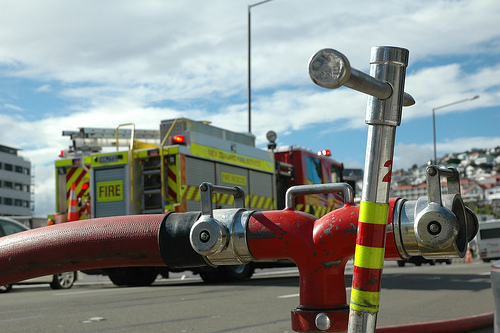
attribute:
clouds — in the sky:
[22, 14, 474, 155]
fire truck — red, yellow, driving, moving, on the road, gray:
[54, 117, 355, 295]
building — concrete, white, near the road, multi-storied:
[0, 145, 39, 220]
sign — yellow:
[97, 178, 123, 202]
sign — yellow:
[222, 175, 246, 187]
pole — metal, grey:
[430, 93, 482, 198]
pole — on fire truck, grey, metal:
[246, 1, 270, 135]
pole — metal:
[310, 42, 416, 330]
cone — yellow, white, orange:
[464, 248, 473, 263]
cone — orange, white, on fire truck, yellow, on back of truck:
[65, 178, 83, 220]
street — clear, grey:
[4, 254, 499, 331]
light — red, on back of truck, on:
[172, 134, 187, 143]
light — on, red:
[323, 149, 332, 158]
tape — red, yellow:
[345, 202, 392, 314]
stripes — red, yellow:
[64, 163, 95, 215]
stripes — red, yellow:
[167, 148, 198, 210]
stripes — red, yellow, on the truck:
[217, 194, 337, 215]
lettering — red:
[99, 185, 121, 199]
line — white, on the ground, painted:
[278, 280, 353, 298]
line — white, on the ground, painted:
[74, 269, 303, 286]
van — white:
[475, 224, 498, 261]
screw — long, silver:
[309, 49, 419, 109]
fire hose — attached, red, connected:
[2, 209, 169, 290]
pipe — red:
[245, 195, 398, 330]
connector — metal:
[192, 180, 257, 271]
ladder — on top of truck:
[66, 125, 165, 145]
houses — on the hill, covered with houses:
[386, 147, 499, 219]